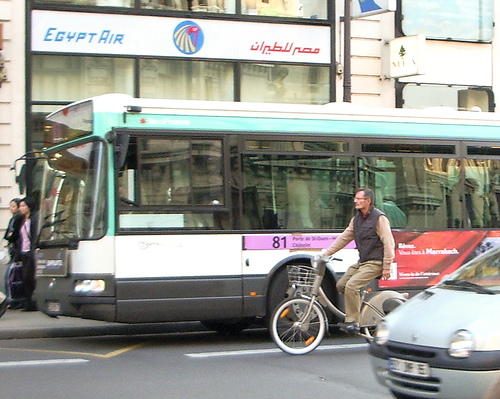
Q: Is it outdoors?
A: Yes, it is outdoors.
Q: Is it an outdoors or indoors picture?
A: It is outdoors.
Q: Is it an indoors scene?
A: No, it is outdoors.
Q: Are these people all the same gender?
A: No, they are both male and female.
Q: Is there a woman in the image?
A: Yes, there is a woman.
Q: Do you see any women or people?
A: Yes, there is a woman.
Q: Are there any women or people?
A: Yes, there is a woman.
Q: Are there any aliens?
A: No, there are no aliens.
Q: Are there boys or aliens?
A: No, there are no aliens or boys.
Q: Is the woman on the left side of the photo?
A: Yes, the woman is on the left of the image.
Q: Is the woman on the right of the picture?
A: No, the woman is on the left of the image.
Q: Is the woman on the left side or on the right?
A: The woman is on the left of the image.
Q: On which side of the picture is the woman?
A: The woman is on the left of the image.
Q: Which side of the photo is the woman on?
A: The woman is on the left of the image.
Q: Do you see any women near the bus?
A: Yes, there is a woman near the bus.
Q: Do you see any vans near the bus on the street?
A: No, there is a woman near the bus.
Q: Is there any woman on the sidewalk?
A: Yes, there is a woman on the sidewalk.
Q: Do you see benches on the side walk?
A: No, there is a woman on the side walk.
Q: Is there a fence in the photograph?
A: No, there are no fences.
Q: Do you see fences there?
A: No, there are no fences.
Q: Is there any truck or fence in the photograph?
A: No, there are no fences or trucks.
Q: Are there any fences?
A: No, there are no fences.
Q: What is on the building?
A: The sign is on the building.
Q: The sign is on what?
A: The sign is on the building.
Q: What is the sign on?
A: The sign is on the building.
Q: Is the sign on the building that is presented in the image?
A: Yes, the sign is on the building.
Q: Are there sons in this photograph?
A: No, there are no sons.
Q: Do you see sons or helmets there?
A: No, there are no sons or helmets.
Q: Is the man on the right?
A: Yes, the man is on the right of the image.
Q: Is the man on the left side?
A: No, the man is on the right of the image.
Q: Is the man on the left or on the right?
A: The man is on the right of the image.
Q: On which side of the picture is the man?
A: The man is on the right of the image.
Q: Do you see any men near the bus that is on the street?
A: Yes, there is a man near the bus.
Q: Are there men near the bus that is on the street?
A: Yes, there is a man near the bus.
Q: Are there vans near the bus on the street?
A: No, there is a man near the bus.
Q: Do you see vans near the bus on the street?
A: No, there is a man near the bus.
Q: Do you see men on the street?
A: Yes, there is a man on the street.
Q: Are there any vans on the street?
A: No, there is a man on the street.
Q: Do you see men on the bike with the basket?
A: Yes, there is a man on the bike.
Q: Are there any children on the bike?
A: No, there is a man on the bike.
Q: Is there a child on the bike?
A: No, there is a man on the bike.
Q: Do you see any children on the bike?
A: No, there is a man on the bike.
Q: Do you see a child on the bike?
A: No, there is a man on the bike.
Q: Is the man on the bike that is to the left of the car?
A: Yes, the man is on the bike.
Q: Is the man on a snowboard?
A: No, the man is on the bike.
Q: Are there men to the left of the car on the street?
A: Yes, there is a man to the left of the car.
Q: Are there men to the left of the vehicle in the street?
A: Yes, there is a man to the left of the car.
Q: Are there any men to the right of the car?
A: No, the man is to the left of the car.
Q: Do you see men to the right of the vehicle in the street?
A: No, the man is to the left of the car.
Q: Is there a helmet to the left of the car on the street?
A: No, there is a man to the left of the car.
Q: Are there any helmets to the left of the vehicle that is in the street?
A: No, there is a man to the left of the car.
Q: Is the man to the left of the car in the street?
A: Yes, the man is to the left of the car.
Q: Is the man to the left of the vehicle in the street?
A: Yes, the man is to the left of the car.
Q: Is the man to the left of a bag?
A: No, the man is to the left of the car.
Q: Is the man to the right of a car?
A: No, the man is to the left of a car.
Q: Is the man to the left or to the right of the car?
A: The man is to the left of the car.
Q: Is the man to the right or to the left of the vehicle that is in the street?
A: The man is to the left of the car.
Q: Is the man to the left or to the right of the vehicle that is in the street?
A: The man is to the left of the car.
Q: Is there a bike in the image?
A: Yes, there is a bike.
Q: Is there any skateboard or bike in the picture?
A: Yes, there is a bike.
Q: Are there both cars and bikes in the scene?
A: Yes, there are both a bike and a car.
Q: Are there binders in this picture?
A: No, there are no binders.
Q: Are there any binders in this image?
A: No, there are no binders.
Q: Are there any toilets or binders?
A: No, there are no binders or toilets.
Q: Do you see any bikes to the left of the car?
A: Yes, there is a bike to the left of the car.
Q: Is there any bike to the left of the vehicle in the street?
A: Yes, there is a bike to the left of the car.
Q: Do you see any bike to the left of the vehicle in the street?
A: Yes, there is a bike to the left of the car.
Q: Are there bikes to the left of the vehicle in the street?
A: Yes, there is a bike to the left of the car.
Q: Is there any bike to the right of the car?
A: No, the bike is to the left of the car.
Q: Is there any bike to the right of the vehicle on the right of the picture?
A: No, the bike is to the left of the car.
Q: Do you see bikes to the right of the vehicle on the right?
A: No, the bike is to the left of the car.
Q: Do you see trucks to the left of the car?
A: No, there is a bike to the left of the car.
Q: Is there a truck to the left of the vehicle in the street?
A: No, there is a bike to the left of the car.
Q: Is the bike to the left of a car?
A: Yes, the bike is to the left of a car.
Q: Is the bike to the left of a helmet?
A: No, the bike is to the left of a car.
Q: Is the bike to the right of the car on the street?
A: No, the bike is to the left of the car.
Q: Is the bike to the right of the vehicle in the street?
A: No, the bike is to the left of the car.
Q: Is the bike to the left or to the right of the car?
A: The bike is to the left of the car.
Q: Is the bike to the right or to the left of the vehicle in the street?
A: The bike is to the left of the car.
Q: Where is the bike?
A: The bike is on the street.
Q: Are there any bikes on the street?
A: Yes, there is a bike on the street.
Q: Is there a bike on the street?
A: Yes, there is a bike on the street.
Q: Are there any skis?
A: No, there are no skis.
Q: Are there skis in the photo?
A: No, there are no skis.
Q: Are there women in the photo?
A: Yes, there is a woman.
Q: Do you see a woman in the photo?
A: Yes, there is a woman.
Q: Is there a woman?
A: Yes, there is a woman.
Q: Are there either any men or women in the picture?
A: Yes, there is a woman.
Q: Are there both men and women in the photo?
A: Yes, there are both a woman and a man.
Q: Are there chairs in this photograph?
A: No, there are no chairs.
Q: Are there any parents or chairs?
A: No, there are no chairs or parents.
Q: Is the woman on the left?
A: Yes, the woman is on the left of the image.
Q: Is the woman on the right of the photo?
A: No, the woman is on the left of the image.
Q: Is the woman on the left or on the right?
A: The woman is on the left of the image.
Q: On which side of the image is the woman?
A: The woman is on the left of the image.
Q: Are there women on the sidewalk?
A: Yes, there is a woman on the sidewalk.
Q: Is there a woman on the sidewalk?
A: Yes, there is a woman on the sidewalk.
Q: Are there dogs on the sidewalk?
A: No, there is a woman on the sidewalk.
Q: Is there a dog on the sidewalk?
A: No, there is a woman on the sidewalk.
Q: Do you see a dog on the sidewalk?
A: No, there is a woman on the sidewalk.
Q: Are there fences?
A: No, there are no fences.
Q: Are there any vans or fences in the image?
A: No, there are no fences or vans.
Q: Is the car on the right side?
A: Yes, the car is on the right of the image.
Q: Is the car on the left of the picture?
A: No, the car is on the right of the image.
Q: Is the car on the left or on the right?
A: The car is on the right of the image.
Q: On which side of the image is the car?
A: The car is on the right of the image.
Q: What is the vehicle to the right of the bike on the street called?
A: The vehicle is a car.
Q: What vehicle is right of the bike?
A: The vehicle is a car.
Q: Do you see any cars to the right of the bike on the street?
A: Yes, there is a car to the right of the bike.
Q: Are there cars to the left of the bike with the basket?
A: No, the car is to the right of the bike.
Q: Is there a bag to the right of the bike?
A: No, there is a car to the right of the bike.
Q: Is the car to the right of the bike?
A: Yes, the car is to the right of the bike.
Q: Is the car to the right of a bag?
A: No, the car is to the right of the bike.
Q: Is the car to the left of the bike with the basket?
A: No, the car is to the right of the bike.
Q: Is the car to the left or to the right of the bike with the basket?
A: The car is to the right of the bike.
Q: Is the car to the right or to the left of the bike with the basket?
A: The car is to the right of the bike.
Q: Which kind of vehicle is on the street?
A: The vehicle is a car.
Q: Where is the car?
A: The car is on the street.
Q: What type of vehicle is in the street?
A: The vehicle is a car.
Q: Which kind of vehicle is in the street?
A: The vehicle is a car.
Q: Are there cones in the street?
A: No, there is a car in the street.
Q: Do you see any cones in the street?
A: No, there is a car in the street.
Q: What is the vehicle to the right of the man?
A: The vehicle is a car.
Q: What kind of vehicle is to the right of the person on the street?
A: The vehicle is a car.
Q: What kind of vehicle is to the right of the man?
A: The vehicle is a car.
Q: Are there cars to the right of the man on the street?
A: Yes, there is a car to the right of the man.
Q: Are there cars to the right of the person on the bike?
A: Yes, there is a car to the right of the man.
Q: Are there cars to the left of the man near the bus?
A: No, the car is to the right of the man.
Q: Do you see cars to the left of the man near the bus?
A: No, the car is to the right of the man.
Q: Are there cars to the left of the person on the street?
A: No, the car is to the right of the man.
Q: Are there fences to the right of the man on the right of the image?
A: No, there is a car to the right of the man.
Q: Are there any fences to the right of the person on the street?
A: No, there is a car to the right of the man.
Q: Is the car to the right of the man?
A: Yes, the car is to the right of the man.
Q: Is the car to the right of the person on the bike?
A: Yes, the car is to the right of the man.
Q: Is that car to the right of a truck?
A: No, the car is to the right of the man.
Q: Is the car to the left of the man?
A: No, the car is to the right of the man.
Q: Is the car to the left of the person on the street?
A: No, the car is to the right of the man.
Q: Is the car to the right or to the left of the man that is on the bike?
A: The car is to the right of the man.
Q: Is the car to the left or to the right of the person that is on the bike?
A: The car is to the right of the man.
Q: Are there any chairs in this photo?
A: No, there are no chairs.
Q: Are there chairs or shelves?
A: No, there are no chairs or shelves.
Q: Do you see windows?
A: Yes, there is a window.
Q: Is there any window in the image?
A: Yes, there is a window.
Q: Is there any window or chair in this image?
A: Yes, there is a window.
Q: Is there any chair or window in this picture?
A: Yes, there is a window.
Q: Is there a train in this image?
A: No, there are no trains.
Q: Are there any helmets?
A: No, there are no helmets.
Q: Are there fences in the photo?
A: No, there are no fences.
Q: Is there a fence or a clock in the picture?
A: No, there are no fences or clocks.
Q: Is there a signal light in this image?
A: No, there are no traffic lights.